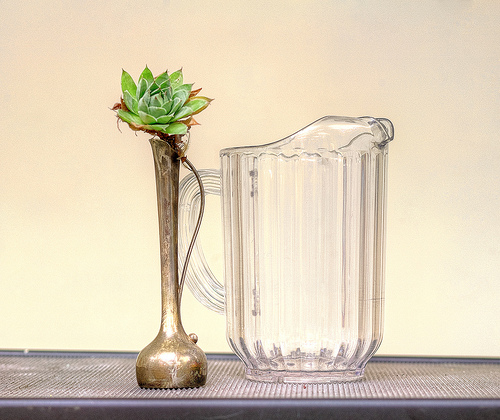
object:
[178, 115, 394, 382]
pitcher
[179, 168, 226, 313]
handle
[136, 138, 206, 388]
vase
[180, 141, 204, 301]
handle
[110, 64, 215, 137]
flower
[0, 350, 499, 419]
table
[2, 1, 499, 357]
wall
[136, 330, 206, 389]
base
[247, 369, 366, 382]
base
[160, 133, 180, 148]
stem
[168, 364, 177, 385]
mark